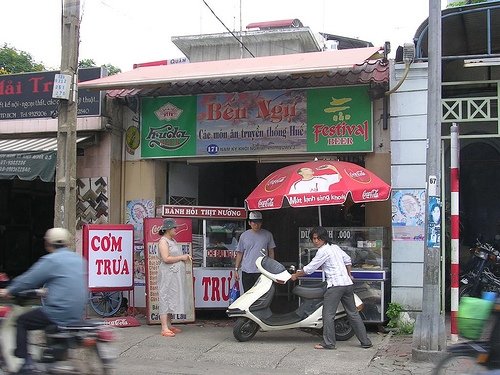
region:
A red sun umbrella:
[244, 157, 391, 230]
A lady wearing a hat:
[154, 215, 191, 337]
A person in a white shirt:
[291, 225, 373, 347]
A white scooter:
[225, 246, 364, 341]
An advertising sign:
[138, 85, 377, 156]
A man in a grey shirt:
[232, 210, 277, 329]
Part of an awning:
[3, 137, 100, 185]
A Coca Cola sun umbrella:
[241, 155, 390, 216]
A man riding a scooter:
[1, 221, 117, 373]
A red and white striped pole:
[448, 120, 460, 337]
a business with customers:
[32, 52, 442, 274]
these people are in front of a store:
[85, 82, 392, 336]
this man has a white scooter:
[225, 229, 375, 342]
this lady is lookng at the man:
[145, 216, 194, 336]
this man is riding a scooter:
[5, 224, 116, 374]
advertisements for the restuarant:
[85, 206, 229, 315]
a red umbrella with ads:
[243, 148, 405, 214]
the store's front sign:
[132, 88, 383, 161]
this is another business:
[1, 61, 103, 322]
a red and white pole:
[428, 120, 469, 345]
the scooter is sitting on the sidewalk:
[253, 256, 290, 292]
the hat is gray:
[158, 213, 178, 235]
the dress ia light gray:
[166, 270, 178, 293]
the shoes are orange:
[160, 323, 182, 341]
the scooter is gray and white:
[256, 260, 284, 294]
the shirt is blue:
[52, 265, 73, 292]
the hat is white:
[46, 223, 68, 245]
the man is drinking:
[299, 163, 330, 178]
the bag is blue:
[223, 285, 243, 305]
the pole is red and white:
[444, 193, 464, 263]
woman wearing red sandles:
[163, 323, 180, 334]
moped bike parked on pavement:
[255, 284, 329, 332]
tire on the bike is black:
[237, 315, 255, 337]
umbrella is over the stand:
[254, 158, 372, 207]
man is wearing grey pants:
[328, 293, 336, 301]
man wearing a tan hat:
[48, 229, 58, 238]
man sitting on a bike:
[58, 327, 94, 372]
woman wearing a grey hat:
[156, 216, 174, 235]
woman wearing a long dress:
[166, 265, 180, 288]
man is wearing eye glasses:
[248, 218, 260, 228]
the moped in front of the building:
[225, 247, 362, 341]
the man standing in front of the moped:
[290, 225, 371, 347]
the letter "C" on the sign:
[91, 235, 100, 250]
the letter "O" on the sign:
[101, 234, 110, 251]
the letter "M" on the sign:
[111, 235, 123, 251]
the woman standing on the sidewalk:
[159, 218, 191, 335]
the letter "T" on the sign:
[94, 258, 105, 274]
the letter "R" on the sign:
[103, 258, 113, 276]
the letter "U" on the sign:
[112, 259, 121, 274]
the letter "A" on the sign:
[121, 258, 130, 275]